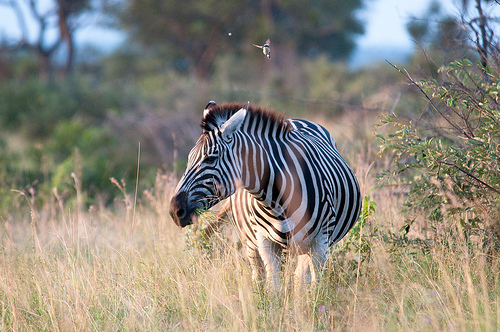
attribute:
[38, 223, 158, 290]
grass — dull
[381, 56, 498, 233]
bush — green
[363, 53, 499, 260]
bush — green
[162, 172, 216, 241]
nose — black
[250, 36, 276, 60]
bird — flying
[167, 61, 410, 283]
zebra — hair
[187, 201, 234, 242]
tail — zebra's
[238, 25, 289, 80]
bird — small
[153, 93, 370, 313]
zebra — brown, white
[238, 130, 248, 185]
stripe — black, white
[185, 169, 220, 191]
stripe — black, white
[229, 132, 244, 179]
stripe — black, white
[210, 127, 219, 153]
stripe — black, white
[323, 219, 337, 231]
stripe — black, white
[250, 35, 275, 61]
hummingbird — small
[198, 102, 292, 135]
hair — mane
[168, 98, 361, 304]
zebra — lovely, eating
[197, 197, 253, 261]
branch — brown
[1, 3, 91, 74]
leafless trees — bare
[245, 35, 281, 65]
bird — small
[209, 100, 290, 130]
mane — black, white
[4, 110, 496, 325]
grass — dry, dead, drying, tall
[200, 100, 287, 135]
mane — short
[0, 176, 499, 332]
grass — tall